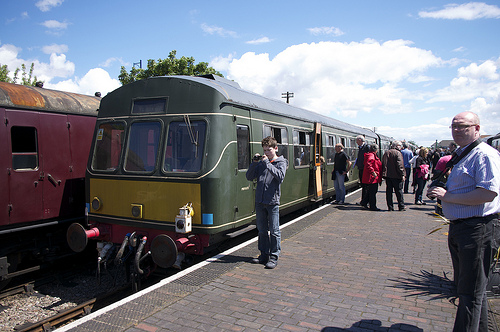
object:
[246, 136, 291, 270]
boy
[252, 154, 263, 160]
phone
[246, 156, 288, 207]
sweater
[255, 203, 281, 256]
boys jeans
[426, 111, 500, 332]
man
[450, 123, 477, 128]
glasses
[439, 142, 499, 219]
shirt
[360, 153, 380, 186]
sweater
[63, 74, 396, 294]
train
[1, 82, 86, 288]
train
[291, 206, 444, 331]
station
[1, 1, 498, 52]
sky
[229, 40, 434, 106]
clouds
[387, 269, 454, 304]
shadow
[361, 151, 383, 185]
jacket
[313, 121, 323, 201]
boarding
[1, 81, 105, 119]
rusty roof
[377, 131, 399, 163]
train cars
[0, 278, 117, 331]
train tracks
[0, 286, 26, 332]
gravel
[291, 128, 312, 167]
passenger windows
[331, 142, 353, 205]
passengers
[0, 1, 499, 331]
train station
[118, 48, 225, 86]
tree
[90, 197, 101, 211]
lights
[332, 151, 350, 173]
shirt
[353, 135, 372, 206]
passengers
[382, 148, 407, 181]
coat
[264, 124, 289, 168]
windows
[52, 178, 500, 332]
platform